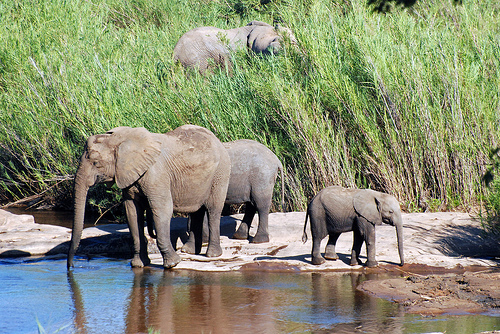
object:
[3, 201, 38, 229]
rock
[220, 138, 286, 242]
elephant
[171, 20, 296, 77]
elephant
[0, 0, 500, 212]
grass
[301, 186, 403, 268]
elephant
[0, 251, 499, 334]
water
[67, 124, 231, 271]
elephant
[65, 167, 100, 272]
trunk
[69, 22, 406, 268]
family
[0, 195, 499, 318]
bank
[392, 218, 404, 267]
trunk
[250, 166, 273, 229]
back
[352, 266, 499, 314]
rocks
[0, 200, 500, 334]
ground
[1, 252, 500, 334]
stream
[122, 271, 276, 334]
reflection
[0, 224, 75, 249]
rocks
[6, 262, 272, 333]
ripples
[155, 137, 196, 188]
wrinkles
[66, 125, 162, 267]
head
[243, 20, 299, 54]
head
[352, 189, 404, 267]
head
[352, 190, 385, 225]
ear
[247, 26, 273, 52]
ear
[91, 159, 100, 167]
eye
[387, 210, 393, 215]
eye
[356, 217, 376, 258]
leg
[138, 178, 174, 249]
leg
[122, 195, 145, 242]
leg